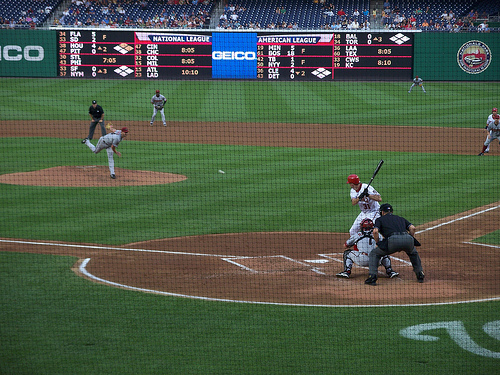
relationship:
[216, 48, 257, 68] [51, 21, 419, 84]
logo on scoreboard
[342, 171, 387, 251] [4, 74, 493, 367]
person on field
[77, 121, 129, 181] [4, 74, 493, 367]
person on field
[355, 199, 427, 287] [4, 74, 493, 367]
person on field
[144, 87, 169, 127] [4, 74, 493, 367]
person on field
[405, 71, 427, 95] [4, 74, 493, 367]
person on field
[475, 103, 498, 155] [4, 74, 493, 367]
person on field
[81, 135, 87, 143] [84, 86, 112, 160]
foot of man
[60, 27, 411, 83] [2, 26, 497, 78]
board on wall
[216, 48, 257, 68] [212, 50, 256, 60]
logo on fence